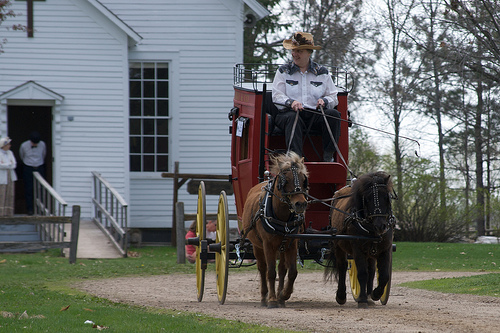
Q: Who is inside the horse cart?
A: A man with a hat.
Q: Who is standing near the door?
A: An old lady and a man.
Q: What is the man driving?
A: A horse carriage.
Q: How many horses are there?
A: Two.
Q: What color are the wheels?
A: Yellow.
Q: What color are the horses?
A: Brown.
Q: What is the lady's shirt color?
A: White.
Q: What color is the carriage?
A: Red.